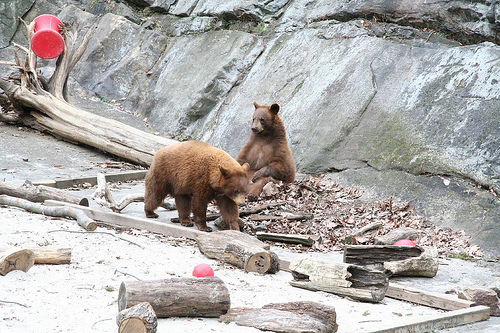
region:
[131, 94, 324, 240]
The two bears on the ground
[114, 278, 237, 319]
The log on the ground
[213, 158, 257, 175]
The ears of the bear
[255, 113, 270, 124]
The eye of the bear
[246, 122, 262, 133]
The nose of the bear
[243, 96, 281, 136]
The head of the bear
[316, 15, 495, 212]
The wall is made of rock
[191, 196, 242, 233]
The front legs of the bear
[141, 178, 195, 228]
The back legs of the bear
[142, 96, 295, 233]
The bears are the color brown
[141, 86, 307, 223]
the bears beside the rock face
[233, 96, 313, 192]
the bear is brown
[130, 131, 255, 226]
the bear is brown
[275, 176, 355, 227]
leaves on the ground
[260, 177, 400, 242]
the leaves are dead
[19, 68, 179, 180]
the large tree trunk on the ground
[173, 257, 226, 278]
red ball on the ground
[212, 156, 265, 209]
the head of the bear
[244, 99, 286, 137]
head of the bear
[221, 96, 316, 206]
the bear is sitting down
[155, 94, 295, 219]
brown bears in rocks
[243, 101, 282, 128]
bear has brown ears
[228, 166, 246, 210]
bear has black nose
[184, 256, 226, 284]
red ball near bears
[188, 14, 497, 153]
grey and stone wall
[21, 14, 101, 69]
red basket in tree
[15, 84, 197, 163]
grey log is downed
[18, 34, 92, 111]
bare branches on log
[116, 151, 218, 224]
bear has brown legs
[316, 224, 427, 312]
log torn into pieces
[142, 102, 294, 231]
The two brown bears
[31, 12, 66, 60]
The red plastic container on the left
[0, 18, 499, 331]
The scattered pieces of wood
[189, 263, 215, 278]
The central red ball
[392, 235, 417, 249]
The blocked red ball on the right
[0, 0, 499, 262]
A sloping rock area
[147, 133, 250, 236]
The walking brown bear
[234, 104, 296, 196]
The sitting brown bear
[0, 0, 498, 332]
A dry dirt covered trench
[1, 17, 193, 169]
The dry fallen tree trunk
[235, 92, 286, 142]
head of a bear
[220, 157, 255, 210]
of a bear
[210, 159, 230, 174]
ear of a bear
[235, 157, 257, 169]
ear of a bear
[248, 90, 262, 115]
ear of a bear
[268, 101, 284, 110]
ear of a bear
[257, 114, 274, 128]
eye of a bear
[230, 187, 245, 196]
eye of a bear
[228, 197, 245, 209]
mouth of a bear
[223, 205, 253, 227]
leg of a bear